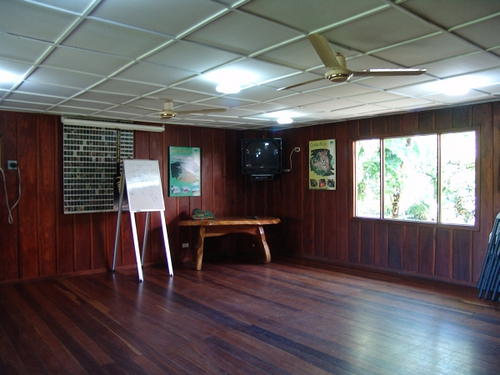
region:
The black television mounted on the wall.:
[242, 135, 286, 180]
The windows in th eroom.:
[347, 133, 489, 235]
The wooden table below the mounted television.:
[178, 205, 290, 273]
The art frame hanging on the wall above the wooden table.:
[166, 144, 214, 204]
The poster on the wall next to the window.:
[301, 134, 343, 198]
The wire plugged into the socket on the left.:
[3, 147, 33, 229]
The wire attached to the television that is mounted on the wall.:
[286, 144, 303, 179]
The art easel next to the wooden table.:
[105, 148, 183, 285]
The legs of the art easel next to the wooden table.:
[115, 222, 180, 277]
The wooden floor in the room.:
[14, 279, 494, 374]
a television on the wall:
[228, 127, 298, 187]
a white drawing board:
[108, 153, 180, 287]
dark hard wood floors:
[291, 275, 377, 353]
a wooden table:
[182, 210, 294, 277]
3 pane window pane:
[346, 134, 483, 238]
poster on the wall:
[163, 145, 208, 211]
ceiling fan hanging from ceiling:
[268, 30, 428, 117]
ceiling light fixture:
[203, 67, 264, 104]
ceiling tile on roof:
[62, 66, 132, 107]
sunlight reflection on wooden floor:
[356, 290, 467, 362]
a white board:
[107, 154, 181, 289]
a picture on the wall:
[55, 127, 133, 218]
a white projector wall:
[49, 112, 170, 141]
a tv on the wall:
[232, 137, 290, 191]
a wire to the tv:
[285, 139, 299, 177]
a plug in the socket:
[295, 142, 300, 154]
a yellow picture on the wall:
[305, 135, 340, 204]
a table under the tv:
[182, 208, 282, 265]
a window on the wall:
[347, 129, 481, 234]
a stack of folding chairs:
[472, 202, 498, 318]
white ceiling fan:
[275, 27, 411, 87]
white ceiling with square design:
[1, 1, 498, 118]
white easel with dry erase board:
[113, 155, 177, 283]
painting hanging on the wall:
[166, 146, 200, 198]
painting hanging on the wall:
[307, 139, 338, 193]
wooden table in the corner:
[181, 210, 279, 265]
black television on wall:
[238, 138, 282, 174]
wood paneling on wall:
[3, 112, 498, 292]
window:
[353, 138, 474, 223]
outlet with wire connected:
[0, 160, 21, 215]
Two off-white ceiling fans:
[120, 25, 438, 127]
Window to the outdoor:
[341, 125, 488, 234]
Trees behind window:
[346, 131, 484, 243]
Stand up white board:
[98, 147, 189, 289]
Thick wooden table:
[172, 205, 285, 277]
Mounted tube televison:
[236, 125, 306, 189]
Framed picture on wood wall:
[299, 134, 346, 204]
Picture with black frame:
[160, 137, 211, 200]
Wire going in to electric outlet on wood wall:
[0, 151, 30, 228]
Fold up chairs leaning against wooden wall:
[473, 206, 499, 307]